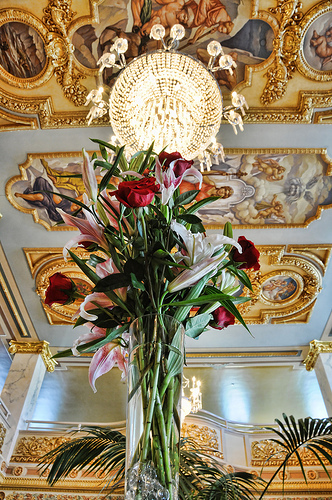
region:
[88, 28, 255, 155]
A large chandelier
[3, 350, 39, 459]
A marble column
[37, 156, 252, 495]
A colorful vase of flowers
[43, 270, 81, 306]
a red rose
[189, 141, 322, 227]
a fresco painted on the ceiling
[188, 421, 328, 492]
Palm branches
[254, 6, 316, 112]
Ornate gilt decoration on the ceiling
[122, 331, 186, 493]
a clear glass vase with bamboo stalks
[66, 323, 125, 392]
A stargazer lily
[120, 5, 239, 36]
figures painted on the ceiling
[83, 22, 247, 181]
Large chandelier hanging from roof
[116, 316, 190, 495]
Clear vase with clear stones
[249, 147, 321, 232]
Two cherubs with god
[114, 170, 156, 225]
Red rose in a boutique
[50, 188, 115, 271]
Lillies in a boutque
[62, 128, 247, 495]
Vase with flowers in foreground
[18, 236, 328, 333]
Decrotive molding on ceiling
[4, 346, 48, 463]
Marble pillar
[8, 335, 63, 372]
Gold valance at the top of pillar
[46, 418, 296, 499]
Decritive palm behind a vase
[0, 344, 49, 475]
a marble pillar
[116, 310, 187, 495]
a clear glass vase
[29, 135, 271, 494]
a floral bouquet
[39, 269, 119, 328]
a red rose on a green stem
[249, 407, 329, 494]
a green leafy palm frond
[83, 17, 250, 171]
the chandelier is lit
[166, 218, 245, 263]
the flower is white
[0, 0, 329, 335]
three painted panels on the ceilling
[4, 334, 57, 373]
the pillar molding is gold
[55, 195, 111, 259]
the flower is pink and white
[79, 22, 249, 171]
Chandelier hanging from ceiling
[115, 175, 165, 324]
Red rose in vase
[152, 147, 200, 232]
Day lily in vase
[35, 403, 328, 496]
Plant fronds behind vase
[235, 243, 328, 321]
Gold decorations on ceiling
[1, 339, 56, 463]
Marble pillar supporting ceiling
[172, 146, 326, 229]
Mural painted on ceiling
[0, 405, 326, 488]
Balcony with ornamental railing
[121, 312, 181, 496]
Clear glass vase with flowers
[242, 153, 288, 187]
Angel on mural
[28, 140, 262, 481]
bouquet of flowers in tall glass vase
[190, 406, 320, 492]
fronds from palm trees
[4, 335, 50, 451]
stone pillar topped with gold ornamentations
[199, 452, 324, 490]
row of gold medallions along terrace wall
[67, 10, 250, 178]
crystal chandelier encircled with candle-like lamps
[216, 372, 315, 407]
ceiling of elevated floor with a terrace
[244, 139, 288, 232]
cherubs on a painted ceiling panel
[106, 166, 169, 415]
long-stemmed red rose in clear container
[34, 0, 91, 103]
overflowing cornucopias in gold relief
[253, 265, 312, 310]
oval painting of heavenly figures in a gold frame